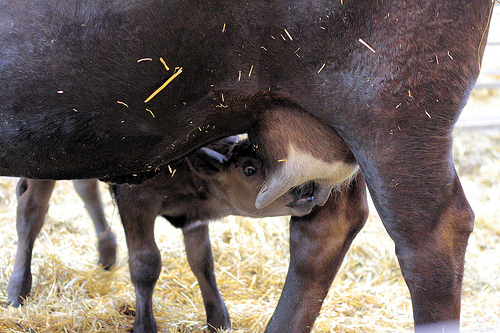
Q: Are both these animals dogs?
A: No, they are dogs and cows.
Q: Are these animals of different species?
A: Yes, they are dogs and cows.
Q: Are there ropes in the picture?
A: No, there are no ropes.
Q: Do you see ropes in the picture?
A: No, there are no ropes.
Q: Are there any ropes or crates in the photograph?
A: No, there are no ropes or crates.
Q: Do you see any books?
A: No, there are no books.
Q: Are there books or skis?
A: No, there are no books or skis.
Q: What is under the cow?
A: The hay is under the cow.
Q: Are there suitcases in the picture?
A: No, there are no suitcases.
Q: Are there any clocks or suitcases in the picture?
A: No, there are no suitcases or clocks.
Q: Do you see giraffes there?
A: No, there are no giraffes.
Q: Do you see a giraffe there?
A: No, there are no giraffes.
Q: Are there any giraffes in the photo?
A: No, there are no giraffes.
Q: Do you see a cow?
A: Yes, there is a cow.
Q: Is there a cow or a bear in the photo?
A: Yes, there is a cow.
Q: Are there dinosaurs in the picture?
A: No, there are no dinosaurs.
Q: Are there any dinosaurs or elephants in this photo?
A: No, there are no dinosaurs or elephants.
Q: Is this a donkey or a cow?
A: This is a cow.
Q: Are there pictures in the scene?
A: No, there are no pictures.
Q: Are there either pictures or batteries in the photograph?
A: No, there are no pictures or batteries.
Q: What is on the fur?
A: The straw is on the fur.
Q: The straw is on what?
A: The straw is on the fur.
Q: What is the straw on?
A: The straw is on the fur.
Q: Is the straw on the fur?
A: Yes, the straw is on the fur.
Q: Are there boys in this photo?
A: No, there are no boys.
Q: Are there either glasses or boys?
A: No, there are no boys or glasses.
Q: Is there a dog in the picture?
A: Yes, there is a dog.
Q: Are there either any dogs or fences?
A: Yes, there is a dog.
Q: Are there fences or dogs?
A: Yes, there is a dog.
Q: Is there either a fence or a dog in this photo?
A: Yes, there is a dog.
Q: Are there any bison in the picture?
A: No, there are no bison.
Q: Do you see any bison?
A: No, there are no bison.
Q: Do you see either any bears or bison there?
A: No, there are no bison or bears.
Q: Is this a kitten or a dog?
A: This is a dog.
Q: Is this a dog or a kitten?
A: This is a dog.